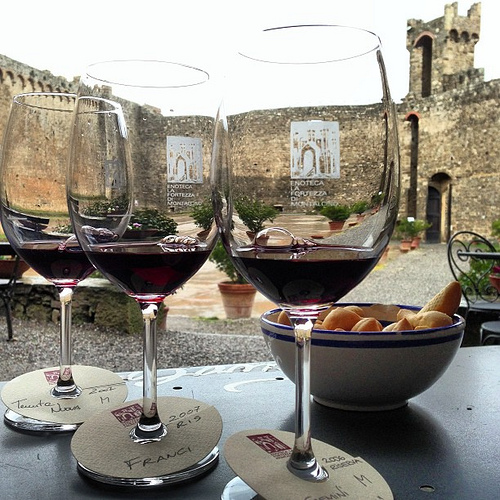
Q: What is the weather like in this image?
A: It is overcast.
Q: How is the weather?
A: It is overcast.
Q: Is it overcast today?
A: Yes, it is overcast.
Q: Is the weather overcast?
A: Yes, it is overcast.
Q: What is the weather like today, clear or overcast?
A: It is overcast.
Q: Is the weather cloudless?
A: No, it is overcast.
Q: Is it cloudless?
A: No, it is overcast.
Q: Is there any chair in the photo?
A: Yes, there is a chair.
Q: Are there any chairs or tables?
A: Yes, there is a chair.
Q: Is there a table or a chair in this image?
A: Yes, there is a chair.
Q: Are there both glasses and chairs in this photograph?
A: Yes, there are both a chair and glasses.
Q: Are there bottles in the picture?
A: No, there are no bottles.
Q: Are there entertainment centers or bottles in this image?
A: No, there are no bottles or entertainment centers.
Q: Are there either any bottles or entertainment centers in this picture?
A: No, there are no bottles or entertainment centers.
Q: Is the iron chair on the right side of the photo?
A: Yes, the chair is on the right of the image.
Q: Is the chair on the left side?
A: No, the chair is on the right of the image.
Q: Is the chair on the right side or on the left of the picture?
A: The chair is on the right of the image.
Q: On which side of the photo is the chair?
A: The chair is on the right of the image.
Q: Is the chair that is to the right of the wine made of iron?
A: Yes, the chair is made of iron.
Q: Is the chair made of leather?
A: No, the chair is made of iron.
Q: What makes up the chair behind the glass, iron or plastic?
A: The chair is made of iron.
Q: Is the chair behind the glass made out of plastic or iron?
A: The chair is made of iron.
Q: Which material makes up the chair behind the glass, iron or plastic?
A: The chair is made of iron.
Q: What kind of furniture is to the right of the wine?
A: The piece of furniture is a chair.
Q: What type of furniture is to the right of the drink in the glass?
A: The piece of furniture is a chair.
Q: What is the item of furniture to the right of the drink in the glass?
A: The piece of furniture is a chair.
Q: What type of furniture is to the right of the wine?
A: The piece of furniture is a chair.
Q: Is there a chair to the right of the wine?
A: Yes, there is a chair to the right of the wine.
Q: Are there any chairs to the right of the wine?
A: Yes, there is a chair to the right of the wine.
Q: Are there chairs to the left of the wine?
A: No, the chair is to the right of the wine.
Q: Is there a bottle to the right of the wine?
A: No, there is a chair to the right of the wine.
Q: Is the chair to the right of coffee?
A: No, the chair is to the right of the wine.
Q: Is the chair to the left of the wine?
A: No, the chair is to the right of the wine.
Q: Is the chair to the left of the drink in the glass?
A: No, the chair is to the right of the wine.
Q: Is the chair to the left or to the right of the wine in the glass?
A: The chair is to the right of the wine.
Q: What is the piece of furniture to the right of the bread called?
A: The piece of furniture is a chair.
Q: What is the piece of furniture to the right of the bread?
A: The piece of furniture is a chair.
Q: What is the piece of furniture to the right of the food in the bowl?
A: The piece of furniture is a chair.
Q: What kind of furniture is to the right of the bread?
A: The piece of furniture is a chair.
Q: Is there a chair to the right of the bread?
A: Yes, there is a chair to the right of the bread.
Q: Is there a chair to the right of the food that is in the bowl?
A: Yes, there is a chair to the right of the bread.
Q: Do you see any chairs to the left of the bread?
A: No, the chair is to the right of the bread.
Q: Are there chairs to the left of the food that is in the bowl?
A: No, the chair is to the right of the bread.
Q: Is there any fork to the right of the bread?
A: No, there is a chair to the right of the bread.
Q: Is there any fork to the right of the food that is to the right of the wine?
A: No, there is a chair to the right of the bread.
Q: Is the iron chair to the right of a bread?
A: Yes, the chair is to the right of a bread.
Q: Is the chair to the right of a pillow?
A: No, the chair is to the right of a bread.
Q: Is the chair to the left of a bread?
A: No, the chair is to the right of a bread.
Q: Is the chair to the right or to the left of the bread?
A: The chair is to the right of the bread.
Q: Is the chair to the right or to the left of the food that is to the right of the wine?
A: The chair is to the right of the bread.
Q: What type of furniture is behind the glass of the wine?
A: The piece of furniture is a chair.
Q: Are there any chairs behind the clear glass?
A: Yes, there is a chair behind the glass.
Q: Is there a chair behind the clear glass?
A: Yes, there is a chair behind the glass.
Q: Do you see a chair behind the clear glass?
A: Yes, there is a chair behind the glass.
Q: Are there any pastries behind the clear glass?
A: No, there is a chair behind the glass.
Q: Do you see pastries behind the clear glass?
A: No, there is a chair behind the glass.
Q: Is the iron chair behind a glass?
A: Yes, the chair is behind a glass.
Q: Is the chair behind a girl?
A: No, the chair is behind a glass.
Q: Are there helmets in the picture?
A: No, there are no helmets.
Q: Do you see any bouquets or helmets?
A: No, there are no helmets or bouquets.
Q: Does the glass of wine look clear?
A: Yes, the glass is clear.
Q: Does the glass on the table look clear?
A: Yes, the glass is clear.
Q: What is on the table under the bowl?
A: The glass is on the table.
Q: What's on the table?
A: The glass is on the table.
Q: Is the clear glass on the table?
A: Yes, the glass is on the table.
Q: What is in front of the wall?
A: The glass is in front of the wall.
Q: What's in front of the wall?
A: The glass is in front of the wall.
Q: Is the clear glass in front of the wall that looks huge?
A: Yes, the glass is in front of the wall.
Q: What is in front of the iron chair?
A: The glass is in front of the chair.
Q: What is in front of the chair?
A: The glass is in front of the chair.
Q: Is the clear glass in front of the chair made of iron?
A: Yes, the glass is in front of the chair.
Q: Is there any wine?
A: Yes, there is wine.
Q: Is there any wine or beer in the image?
A: Yes, there is wine.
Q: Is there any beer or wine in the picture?
A: Yes, there is wine.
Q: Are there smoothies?
A: No, there are no smoothies.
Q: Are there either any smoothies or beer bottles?
A: No, there are no smoothies or beer bottles.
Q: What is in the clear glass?
A: The wine is in the glass.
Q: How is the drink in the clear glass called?
A: The drink is wine.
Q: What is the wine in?
A: The wine is in the glass.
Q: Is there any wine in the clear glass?
A: Yes, there is wine in the glass.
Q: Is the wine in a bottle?
A: No, the wine is in a glass.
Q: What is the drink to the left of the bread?
A: The drink is wine.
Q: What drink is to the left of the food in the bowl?
A: The drink is wine.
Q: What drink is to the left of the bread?
A: The drink is wine.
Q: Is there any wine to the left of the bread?
A: Yes, there is wine to the left of the bread.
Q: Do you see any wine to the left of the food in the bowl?
A: Yes, there is wine to the left of the bread.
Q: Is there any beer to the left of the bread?
A: No, there is wine to the left of the bread.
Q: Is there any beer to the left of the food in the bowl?
A: No, there is wine to the left of the bread.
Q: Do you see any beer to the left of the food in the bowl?
A: No, there is wine to the left of the bread.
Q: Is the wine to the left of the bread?
A: Yes, the wine is to the left of the bread.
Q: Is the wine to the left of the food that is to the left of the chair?
A: Yes, the wine is to the left of the bread.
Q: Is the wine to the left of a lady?
A: No, the wine is to the left of the bread.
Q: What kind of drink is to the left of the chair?
A: The drink is wine.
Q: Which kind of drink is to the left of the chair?
A: The drink is wine.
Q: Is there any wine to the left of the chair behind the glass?
A: Yes, there is wine to the left of the chair.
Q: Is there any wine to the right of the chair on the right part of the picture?
A: No, the wine is to the left of the chair.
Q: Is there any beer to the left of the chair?
A: No, there is wine to the left of the chair.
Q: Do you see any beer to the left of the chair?
A: No, there is wine to the left of the chair.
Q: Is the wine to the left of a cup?
A: No, the wine is to the left of a chair.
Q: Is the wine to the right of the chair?
A: No, the wine is to the left of the chair.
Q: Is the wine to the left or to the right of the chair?
A: The wine is to the left of the chair.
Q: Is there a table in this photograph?
A: Yes, there is a table.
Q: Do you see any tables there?
A: Yes, there is a table.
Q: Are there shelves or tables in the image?
A: Yes, there is a table.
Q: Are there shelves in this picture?
A: No, there are no shelves.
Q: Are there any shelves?
A: No, there are no shelves.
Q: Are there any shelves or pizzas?
A: No, there are no shelves or pizzas.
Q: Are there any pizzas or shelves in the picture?
A: No, there are no shelves or pizzas.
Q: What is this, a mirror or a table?
A: This is a table.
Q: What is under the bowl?
A: The table is under the bowl.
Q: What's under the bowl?
A: The table is under the bowl.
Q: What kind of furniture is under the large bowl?
A: The piece of furniture is a table.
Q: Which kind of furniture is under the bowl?
A: The piece of furniture is a table.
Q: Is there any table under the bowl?
A: Yes, there is a table under the bowl.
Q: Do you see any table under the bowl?
A: Yes, there is a table under the bowl.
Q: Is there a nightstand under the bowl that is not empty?
A: No, there is a table under the bowl.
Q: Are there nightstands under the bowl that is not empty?
A: No, there is a table under the bowl.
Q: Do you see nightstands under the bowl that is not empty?
A: No, there is a table under the bowl.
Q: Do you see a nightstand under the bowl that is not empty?
A: No, there is a table under the bowl.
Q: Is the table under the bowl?
A: Yes, the table is under the bowl.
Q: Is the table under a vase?
A: No, the table is under the bowl.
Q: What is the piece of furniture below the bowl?
A: The piece of furniture is a table.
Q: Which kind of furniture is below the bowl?
A: The piece of furniture is a table.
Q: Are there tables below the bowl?
A: Yes, there is a table below the bowl.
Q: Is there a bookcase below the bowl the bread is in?
A: No, there is a table below the bowl.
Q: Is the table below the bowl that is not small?
A: Yes, the table is below the bowl.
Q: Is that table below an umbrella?
A: No, the table is below the bowl.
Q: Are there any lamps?
A: No, there are no lamps.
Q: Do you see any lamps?
A: No, there are no lamps.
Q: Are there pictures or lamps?
A: No, there are no lamps or pictures.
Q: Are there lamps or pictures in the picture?
A: No, there are no lamps or pictures.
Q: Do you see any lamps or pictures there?
A: No, there are no lamps or pictures.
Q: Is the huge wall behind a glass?
A: Yes, the wall is behind a glass.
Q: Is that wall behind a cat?
A: No, the wall is behind a glass.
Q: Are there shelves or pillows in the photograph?
A: No, there are no shelves or pillows.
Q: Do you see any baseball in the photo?
A: No, there are no baseballs.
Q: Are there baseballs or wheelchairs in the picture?
A: No, there are no baseballs or wheelchairs.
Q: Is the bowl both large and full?
A: Yes, the bowl is large and full.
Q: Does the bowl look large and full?
A: Yes, the bowl is large and full.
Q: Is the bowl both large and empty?
A: No, the bowl is large but full.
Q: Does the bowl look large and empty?
A: No, the bowl is large but full.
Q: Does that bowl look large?
A: Yes, the bowl is large.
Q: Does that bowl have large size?
A: Yes, the bowl is large.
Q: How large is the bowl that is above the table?
A: The bowl is large.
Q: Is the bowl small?
A: No, the bowl is large.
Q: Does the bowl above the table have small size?
A: No, the bowl is large.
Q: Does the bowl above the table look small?
A: No, the bowl is large.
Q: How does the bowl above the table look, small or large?
A: The bowl is large.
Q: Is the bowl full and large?
A: Yes, the bowl is full and large.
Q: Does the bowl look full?
A: Yes, the bowl is full.